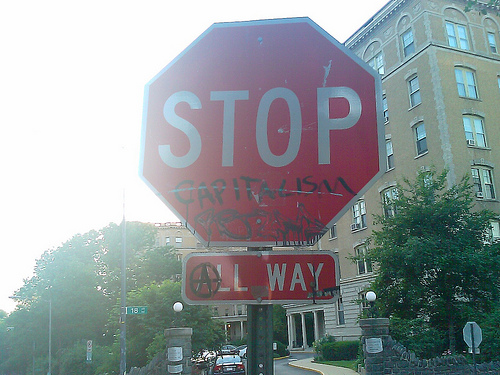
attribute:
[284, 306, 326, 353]
columns — white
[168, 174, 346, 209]
graffiti — black, white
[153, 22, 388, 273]
stop sign — red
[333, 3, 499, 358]
building — large, distant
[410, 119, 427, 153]
window — white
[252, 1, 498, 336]
building — large, tan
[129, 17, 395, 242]
stop sign — white, red, large, spraypainted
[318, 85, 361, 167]
letter — white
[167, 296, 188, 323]
light — white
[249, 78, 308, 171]
letter o — white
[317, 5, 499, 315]
building — brown, tall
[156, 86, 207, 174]
letter — white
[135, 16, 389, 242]
sign — red